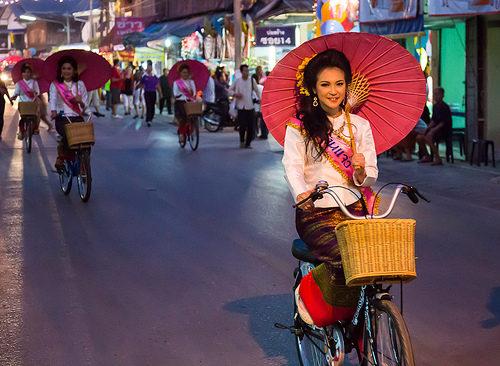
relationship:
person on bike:
[294, 45, 381, 197] [289, 247, 417, 360]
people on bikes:
[17, 50, 230, 148] [165, 110, 249, 150]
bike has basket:
[289, 247, 417, 360] [329, 215, 421, 282]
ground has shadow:
[119, 189, 235, 283] [236, 286, 273, 333]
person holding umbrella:
[280, 48, 379, 365] [381, 61, 431, 110]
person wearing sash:
[280, 48, 379, 365] [318, 134, 352, 164]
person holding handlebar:
[280, 48, 379, 365] [303, 190, 347, 213]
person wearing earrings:
[280, 48, 379, 365] [307, 99, 320, 112]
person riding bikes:
[280, 48, 379, 365] [165, 110, 249, 150]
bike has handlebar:
[289, 247, 417, 360] [303, 190, 347, 213]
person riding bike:
[280, 48, 379, 365] [289, 247, 417, 360]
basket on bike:
[329, 215, 421, 282] [289, 247, 417, 360]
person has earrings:
[280, 48, 379, 365] [307, 99, 320, 112]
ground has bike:
[119, 189, 235, 283] [289, 247, 417, 360]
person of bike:
[280, 48, 379, 365] [289, 247, 417, 360]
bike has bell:
[289, 247, 417, 360] [309, 180, 328, 200]